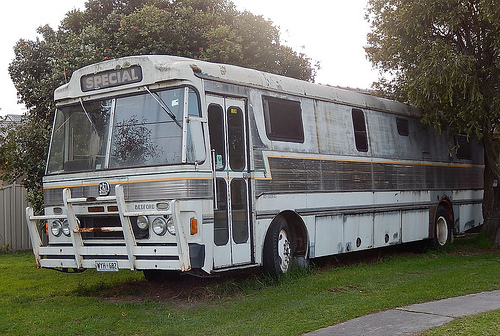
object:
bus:
[23, 53, 488, 281]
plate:
[95, 259, 121, 273]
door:
[206, 95, 261, 276]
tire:
[257, 218, 296, 284]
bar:
[77, 226, 125, 234]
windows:
[260, 93, 308, 145]